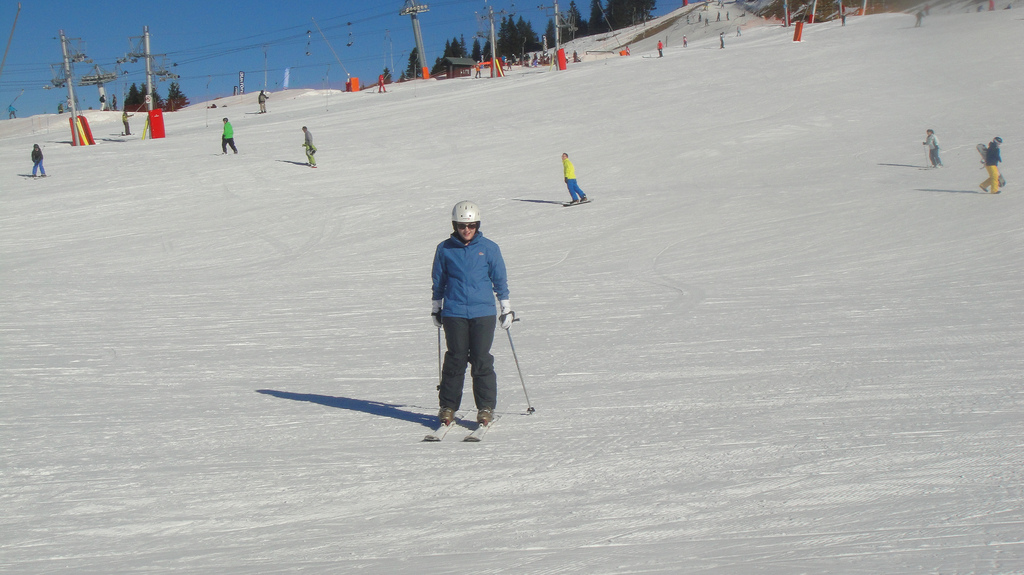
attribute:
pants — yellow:
[982, 161, 1003, 199]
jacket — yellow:
[562, 161, 578, 181]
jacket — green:
[219, 122, 233, 143]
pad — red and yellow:
[69, 114, 95, 150]